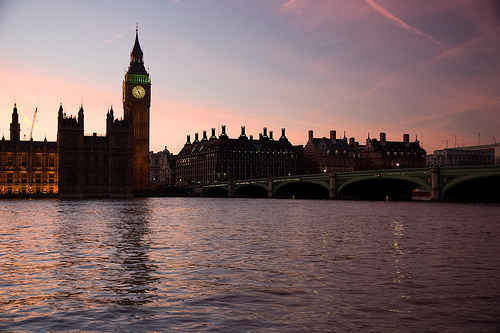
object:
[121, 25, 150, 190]
tower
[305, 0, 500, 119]
clouds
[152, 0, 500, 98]
sky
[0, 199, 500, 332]
water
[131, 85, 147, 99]
clock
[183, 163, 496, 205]
bridge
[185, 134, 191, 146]
chimney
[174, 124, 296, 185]
building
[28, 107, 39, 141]
crane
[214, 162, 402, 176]
lights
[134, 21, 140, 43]
peak